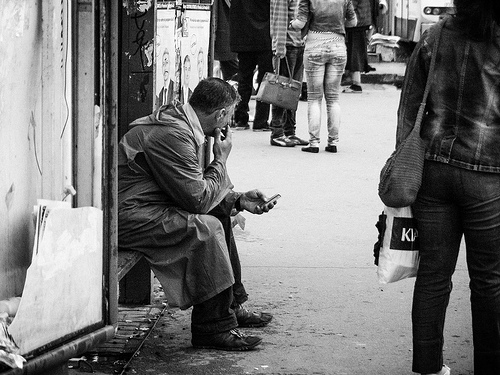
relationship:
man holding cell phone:
[114, 78, 274, 352] [261, 192, 283, 211]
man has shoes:
[114, 78, 274, 352] [200, 301, 275, 354]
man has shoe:
[114, 78, 274, 352] [238, 304, 275, 328]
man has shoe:
[114, 78, 274, 352] [188, 326, 264, 348]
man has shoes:
[114, 78, 274, 352] [191, 307, 278, 357]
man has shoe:
[114, 78, 274, 352] [229, 307, 275, 325]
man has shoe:
[114, 78, 274, 352] [195, 327, 267, 354]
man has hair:
[118, 77, 275, 350] [188, 75, 238, 117]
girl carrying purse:
[393, 0, 498, 374] [378, 21, 446, 210]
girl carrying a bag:
[393, 0, 498, 374] [373, 126, 431, 206]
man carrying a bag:
[269, 0, 309, 148] [257, 71, 299, 113]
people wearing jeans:
[285, 0, 359, 153] [300, 28, 351, 149]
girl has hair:
[393, 0, 498, 374] [443, 0, 499, 84]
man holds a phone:
[118, 77, 275, 350] [256, 189, 280, 213]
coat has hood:
[118, 103, 238, 310] [133, 107, 179, 131]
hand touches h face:
[213, 125, 233, 157] [210, 88, 242, 150]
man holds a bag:
[269, 0, 309, 148] [255, 55, 302, 111]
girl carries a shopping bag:
[393, 0, 498, 374] [350, 188, 437, 310]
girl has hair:
[393, 0, 498, 374] [439, 8, 499, 145]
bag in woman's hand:
[252, 77, 303, 108] [263, 43, 292, 65]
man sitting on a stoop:
[118, 77, 275, 350] [100, 234, 161, 314]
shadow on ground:
[151, 339, 200, 373] [138, 297, 221, 373]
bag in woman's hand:
[375, 204, 420, 286] [372, 137, 426, 240]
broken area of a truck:
[21, 183, 130, 346] [0, 6, 145, 357]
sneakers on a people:
[264, 128, 308, 155] [285, 0, 359, 153]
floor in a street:
[103, 300, 183, 357] [134, 169, 434, 371]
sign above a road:
[421, 0, 453, 19] [360, 54, 412, 176]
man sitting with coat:
[118, 77, 275, 350] [118, 126, 234, 324]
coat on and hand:
[118, 126, 234, 324] [211, 123, 234, 155]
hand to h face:
[211, 123, 234, 155] [213, 98, 238, 144]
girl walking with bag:
[393, 0, 498, 374] [377, 16, 449, 208]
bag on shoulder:
[377, 16, 449, 208] [391, 30, 459, 86]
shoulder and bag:
[391, 30, 459, 86] [375, 204, 420, 286]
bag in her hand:
[375, 204, 420, 286] [376, 172, 425, 233]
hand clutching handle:
[213, 125, 233, 157] [270, 52, 291, 76]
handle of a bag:
[270, 52, 291, 76] [255, 55, 302, 111]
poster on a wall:
[154, 9, 213, 109] [153, 5, 215, 120]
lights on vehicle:
[425, 6, 443, 16] [381, 1, 451, 41]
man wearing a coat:
[114, 78, 274, 352] [118, 103, 238, 310]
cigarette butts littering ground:
[65, 283, 187, 373] [32, 83, 475, 370]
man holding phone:
[118, 77, 275, 350] [247, 180, 280, 225]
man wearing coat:
[118, 77, 275, 350] [110, 90, 243, 307]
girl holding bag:
[393, 0, 498, 374] [363, 177, 420, 281]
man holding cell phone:
[118, 77, 275, 350] [261, 193, 282, 211]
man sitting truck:
[118, 77, 275, 350] [5, 4, 203, 336]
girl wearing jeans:
[374, 7, 484, 332] [384, 170, 484, 347]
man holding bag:
[256, 1, 306, 149] [256, 57, 302, 107]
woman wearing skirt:
[349, 1, 379, 94] [350, 12, 375, 70]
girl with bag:
[393, 0, 498, 374] [380, 52, 435, 199]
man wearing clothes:
[218, 11, 276, 131] [212, 23, 262, 56]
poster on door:
[158, 16, 207, 83] [157, 8, 185, 115]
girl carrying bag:
[393, 0, 498, 374] [372, 37, 434, 209]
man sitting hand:
[118, 77, 275, 350] [204, 124, 233, 204]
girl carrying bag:
[393, 0, 498, 374] [377, 16, 449, 208]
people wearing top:
[285, 0, 359, 153] [294, 1, 359, 38]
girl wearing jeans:
[393, 0, 498, 374] [381, 11, 481, 372]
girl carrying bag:
[393, 0, 498, 374] [373, 198, 427, 286]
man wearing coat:
[118, 77, 275, 350] [121, 97, 243, 266]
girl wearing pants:
[393, 0, 498, 374] [392, 172, 483, 358]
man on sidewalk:
[220, 0, 273, 132] [277, 233, 367, 346]